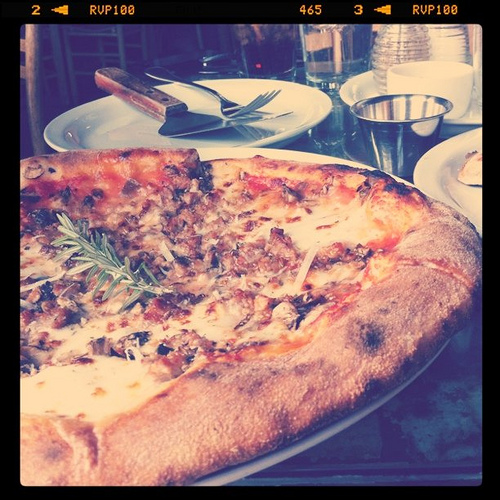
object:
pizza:
[16, 148, 478, 485]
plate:
[83, 146, 480, 484]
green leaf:
[54, 206, 176, 301]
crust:
[254, 260, 481, 452]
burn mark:
[354, 318, 391, 352]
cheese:
[35, 360, 145, 414]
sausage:
[174, 207, 293, 286]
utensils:
[89, 51, 281, 137]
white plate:
[43, 79, 333, 152]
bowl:
[349, 93, 454, 179]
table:
[15, 47, 484, 486]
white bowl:
[387, 64, 476, 121]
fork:
[144, 69, 299, 122]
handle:
[86, 61, 192, 114]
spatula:
[94, 66, 263, 139]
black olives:
[153, 344, 174, 358]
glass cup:
[291, 21, 367, 89]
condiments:
[239, 20, 294, 75]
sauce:
[36, 153, 161, 212]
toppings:
[28, 158, 210, 346]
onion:
[295, 227, 336, 294]